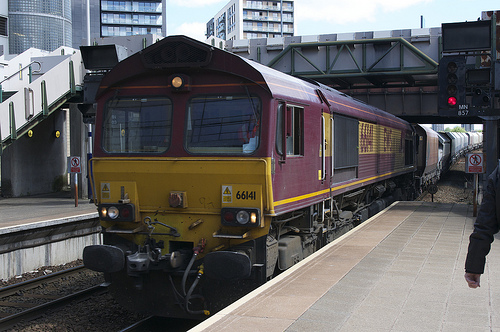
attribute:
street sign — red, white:
[466, 154, 482, 171]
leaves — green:
[439, 121, 467, 133]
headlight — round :
[92, 187, 284, 238]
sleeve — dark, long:
[466, 165, 496, 287]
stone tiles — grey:
[373, 265, 448, 317]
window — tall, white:
[271, 0, 278, 8]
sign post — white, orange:
[59, 149, 86, 206]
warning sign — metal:
[462, 145, 487, 176]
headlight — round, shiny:
[224, 205, 264, 231]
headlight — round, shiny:
[95, 198, 124, 225]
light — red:
[447, 96, 462, 106]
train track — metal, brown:
[112, 307, 155, 330]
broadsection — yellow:
[260, 149, 402, 299]